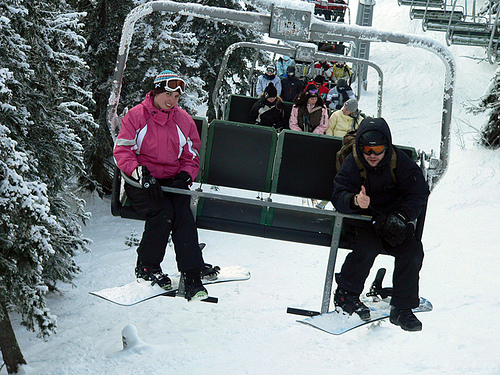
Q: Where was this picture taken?
A: On a ski lift.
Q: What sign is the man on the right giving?
A: Thumbs up.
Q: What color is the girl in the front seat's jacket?
A: Pink.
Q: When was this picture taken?
A: Winter time.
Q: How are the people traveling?
A: Via ski lift.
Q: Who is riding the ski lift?
A: Skiers.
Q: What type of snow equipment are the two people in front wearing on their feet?
A: Snowboards.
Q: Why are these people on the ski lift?
A: To get to the top of the runs.